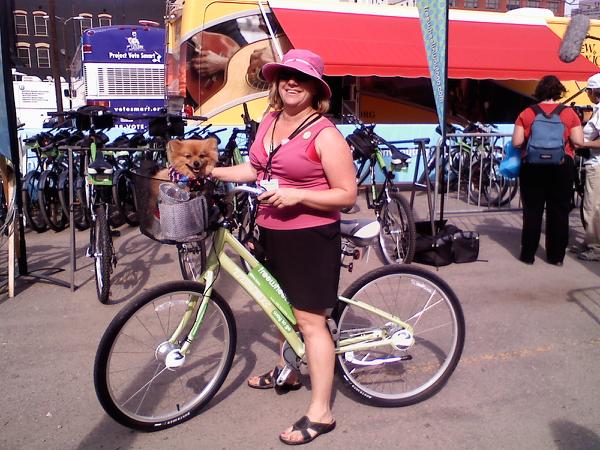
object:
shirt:
[248, 112, 336, 230]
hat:
[261, 48, 330, 102]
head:
[277, 49, 318, 113]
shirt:
[514, 103, 580, 160]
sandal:
[248, 369, 301, 390]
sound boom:
[557, 14, 590, 64]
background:
[0, 0, 599, 245]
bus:
[68, 25, 166, 130]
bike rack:
[0, 136, 437, 237]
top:
[214, 107, 356, 231]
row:
[16, 125, 257, 231]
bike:
[18, 133, 61, 233]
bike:
[34, 119, 61, 233]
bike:
[58, 124, 85, 229]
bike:
[129, 116, 206, 224]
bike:
[110, 111, 144, 226]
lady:
[513, 74, 584, 267]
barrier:
[430, 133, 578, 214]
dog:
[148, 138, 218, 215]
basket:
[122, 164, 215, 245]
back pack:
[526, 99, 567, 165]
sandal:
[279, 415, 337, 446]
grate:
[83, 63, 168, 99]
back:
[29, 27, 167, 126]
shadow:
[547, 418, 600, 449]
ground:
[483, 363, 569, 446]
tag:
[235, 185, 263, 196]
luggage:
[393, 219, 480, 267]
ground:
[470, 270, 600, 386]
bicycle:
[93, 166, 466, 433]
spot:
[92, 283, 516, 447]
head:
[165, 137, 218, 178]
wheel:
[332, 263, 465, 407]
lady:
[210, 48, 359, 443]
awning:
[266, 7, 600, 79]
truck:
[161, 0, 599, 193]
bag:
[345, 126, 378, 167]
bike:
[342, 115, 417, 270]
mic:
[557, 14, 599, 63]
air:
[504, 4, 548, 67]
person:
[568, 74, 600, 262]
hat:
[584, 72, 600, 88]